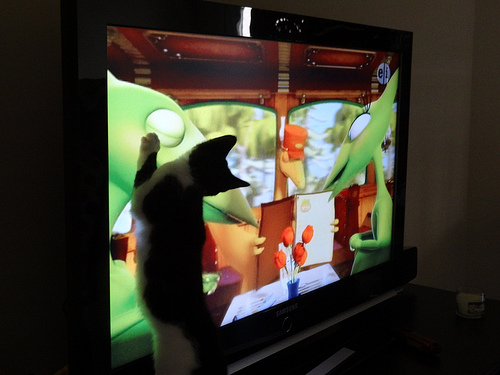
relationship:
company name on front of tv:
[274, 297, 303, 318] [58, 0, 420, 374]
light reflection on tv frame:
[236, 4, 255, 38] [58, 0, 420, 374]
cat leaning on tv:
[132, 113, 252, 372] [58, 0, 420, 374]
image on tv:
[103, 24, 402, 369] [58, 0, 420, 374]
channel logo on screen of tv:
[374, 62, 395, 85] [58, 0, 420, 374]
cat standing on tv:
[132, 113, 252, 372] [58, 0, 420, 374]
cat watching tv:
[132, 113, 252, 372] [58, 0, 420, 374]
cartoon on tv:
[103, 24, 402, 369] [58, 0, 420, 374]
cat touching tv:
[132, 113, 252, 372] [58, 0, 420, 374]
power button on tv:
[281, 312, 296, 335] [58, 0, 420, 374]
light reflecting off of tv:
[236, 4, 255, 38] [58, 0, 420, 374]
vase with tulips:
[286, 276, 302, 300] [270, 222, 315, 281]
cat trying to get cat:
[132, 113, 252, 372] [132, 132, 250, 372]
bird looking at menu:
[247, 122, 343, 255] [256, 189, 336, 288]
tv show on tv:
[103, 24, 402, 369] [58, 0, 420, 374]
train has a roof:
[103, 24, 402, 369] [107, 26, 396, 96]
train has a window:
[58, 0, 420, 374] [187, 105, 278, 208]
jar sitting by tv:
[456, 282, 487, 322] [58, 0, 420, 374]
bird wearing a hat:
[247, 122, 343, 255] [283, 120, 307, 160]